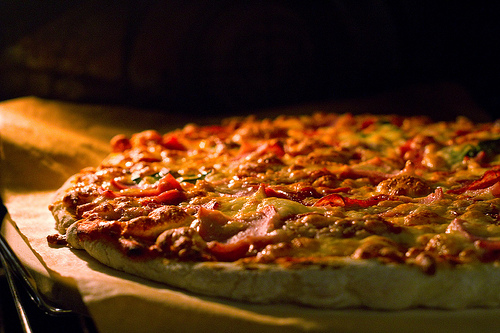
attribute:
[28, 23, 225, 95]
brick — Dark 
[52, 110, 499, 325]
pizza — displayed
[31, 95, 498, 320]
pizza — circle